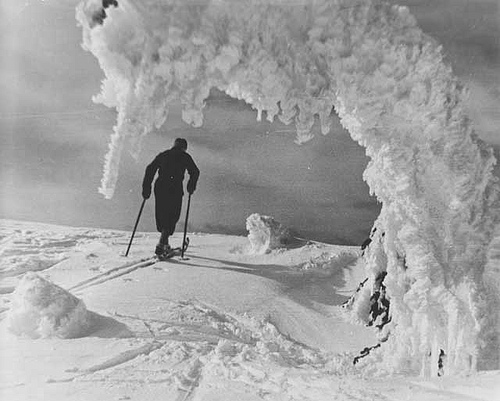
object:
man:
[142, 137, 200, 255]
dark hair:
[175, 138, 184, 149]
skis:
[154, 246, 182, 260]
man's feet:
[155, 243, 171, 255]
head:
[174, 137, 186, 151]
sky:
[0, 0, 499, 248]